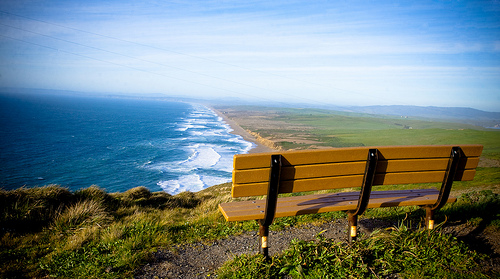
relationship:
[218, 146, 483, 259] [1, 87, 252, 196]
bench facing sea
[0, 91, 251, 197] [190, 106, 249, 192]
ocean has waves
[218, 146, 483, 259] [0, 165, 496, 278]
bench on a cliff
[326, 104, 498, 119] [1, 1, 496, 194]
mountain are in distance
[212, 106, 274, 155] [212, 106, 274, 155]
beach on beach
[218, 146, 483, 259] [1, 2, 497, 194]
bench has a view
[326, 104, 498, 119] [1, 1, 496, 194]
mountain in distance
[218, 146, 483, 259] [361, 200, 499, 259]
bench has a shadow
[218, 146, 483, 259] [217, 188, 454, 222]
bench has a seat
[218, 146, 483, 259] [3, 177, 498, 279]
bench next to grass